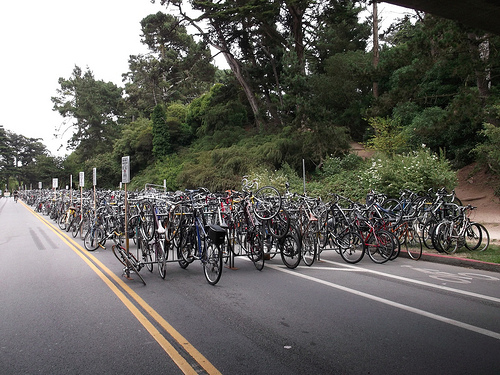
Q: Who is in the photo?
A: One person.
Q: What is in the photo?
A: Bikes.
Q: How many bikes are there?
A: More than ten.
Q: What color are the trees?
A: Green.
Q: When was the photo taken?
A: Daytime.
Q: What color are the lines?
A: Yellow.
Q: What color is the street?
A: Black.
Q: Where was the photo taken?
A: On a street with parked bikes.